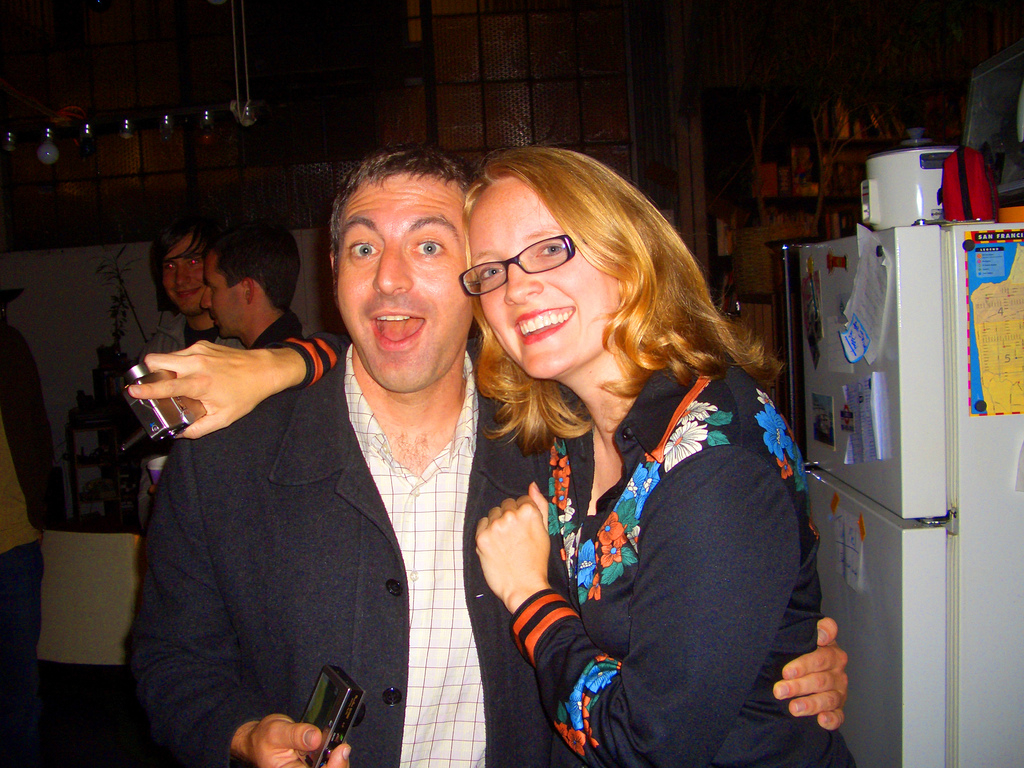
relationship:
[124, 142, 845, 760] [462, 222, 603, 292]
woman wearing eyeglasses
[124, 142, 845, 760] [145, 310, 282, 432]
woman in hand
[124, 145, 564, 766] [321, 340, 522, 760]
man wearing shirt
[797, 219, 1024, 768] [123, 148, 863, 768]
fridge behind woman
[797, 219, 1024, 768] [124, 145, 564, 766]
fridge behind man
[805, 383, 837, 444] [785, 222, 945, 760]
magnets are on door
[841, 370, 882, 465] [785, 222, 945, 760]
paper are on door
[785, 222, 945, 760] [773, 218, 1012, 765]
door on refrigerator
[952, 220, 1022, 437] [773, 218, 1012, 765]
magnet on refrigerator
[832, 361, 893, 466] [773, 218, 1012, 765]
paper on refrigerator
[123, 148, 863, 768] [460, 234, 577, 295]
woman wearing eyeglasses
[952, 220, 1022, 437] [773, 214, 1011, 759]
magnet on fridge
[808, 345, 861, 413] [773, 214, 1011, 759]
magnet on fridge